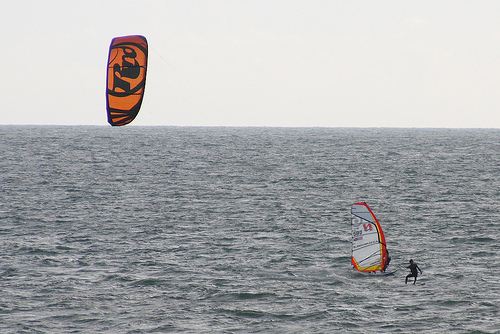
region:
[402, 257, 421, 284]
person surfsailing in the water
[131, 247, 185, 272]
choppy dark water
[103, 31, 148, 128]
orange and red parasail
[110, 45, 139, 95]
black lettering on parasail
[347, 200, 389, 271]
orange and white sail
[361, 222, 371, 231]
orange numbers on sail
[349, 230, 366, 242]
black lettering on side of sail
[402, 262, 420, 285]
black wetsuit on person in water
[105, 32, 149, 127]
black trim around parasail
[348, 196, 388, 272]
orange trim around white sail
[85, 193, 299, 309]
Water is dark blue in color.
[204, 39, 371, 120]
Sky is light and bright.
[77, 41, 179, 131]
Black and yellow object in water.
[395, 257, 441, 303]
Person wearing wet suit.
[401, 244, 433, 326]
Wet suit is dark in color.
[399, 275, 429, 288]
Person is standing on something in water.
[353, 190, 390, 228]
Red edging on sail in water.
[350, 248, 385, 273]
Yellow strip on sail in water.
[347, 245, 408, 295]
Sail connected to board in water.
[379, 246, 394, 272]
Person standing on board in water.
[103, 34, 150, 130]
a giant black and orange kite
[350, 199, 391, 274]
an orange white and grey wind sail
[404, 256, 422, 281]
a person standing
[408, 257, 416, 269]
the head of a person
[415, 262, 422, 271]
the arm of a person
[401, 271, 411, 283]
the leg of a person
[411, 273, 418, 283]
the leg of a person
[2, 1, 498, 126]
the overcast sky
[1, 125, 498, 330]
the grey blue ocean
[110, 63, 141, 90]
a black letter R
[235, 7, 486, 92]
this is the sky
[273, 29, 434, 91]
the sky is full of clouds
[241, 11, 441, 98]
the sky is white in color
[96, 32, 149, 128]
this is a kite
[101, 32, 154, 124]
the kite is big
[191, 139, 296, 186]
this is the water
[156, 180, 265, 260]
the water is blue in color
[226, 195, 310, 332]
the water has some ripples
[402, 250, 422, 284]
this is a person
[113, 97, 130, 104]
the kite is orange in color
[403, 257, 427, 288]
this is a man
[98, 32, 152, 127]
the kite is orange in color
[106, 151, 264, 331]
the waves are small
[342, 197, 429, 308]
the man is sea surfing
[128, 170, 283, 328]
the water is grey in color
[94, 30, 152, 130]
the kite is big in size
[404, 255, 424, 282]
the man is in motion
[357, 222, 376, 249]
the kite is white in color